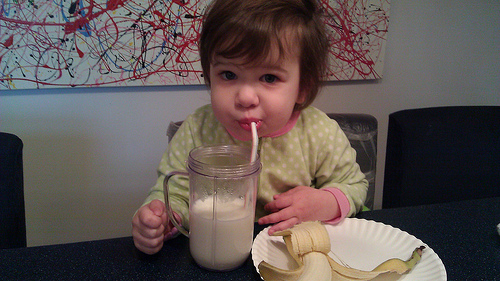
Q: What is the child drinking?
A: Milk.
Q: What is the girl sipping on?
A: A straw.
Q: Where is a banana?
A: On paper plate.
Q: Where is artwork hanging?
A: On the wall.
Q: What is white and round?
A: Paper plate.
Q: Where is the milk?
A: In a cup.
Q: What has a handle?
A: The cup.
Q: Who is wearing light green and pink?
A: Little girl.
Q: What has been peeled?
A: Banana.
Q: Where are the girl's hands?
A: On table.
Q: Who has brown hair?
A: The young girl.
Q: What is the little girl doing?
A: Drinking milk.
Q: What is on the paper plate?
A: Banana.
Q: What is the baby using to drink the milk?
A: Straw.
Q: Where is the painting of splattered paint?
A: On the wall.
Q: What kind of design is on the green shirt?
A: White polka dots.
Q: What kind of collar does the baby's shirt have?
A: Round pink collar.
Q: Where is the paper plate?
A: On the black counter.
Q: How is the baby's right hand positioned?
A: In a fist.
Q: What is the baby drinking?
A: Milk.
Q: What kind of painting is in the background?
A: Abstract.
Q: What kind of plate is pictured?
A: Paper.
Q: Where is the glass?
A: On the table.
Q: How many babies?
A: 1.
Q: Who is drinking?
A: The baby.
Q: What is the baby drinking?
A: Milk.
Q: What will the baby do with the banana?
A: Eat it.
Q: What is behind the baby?
A: Painting.